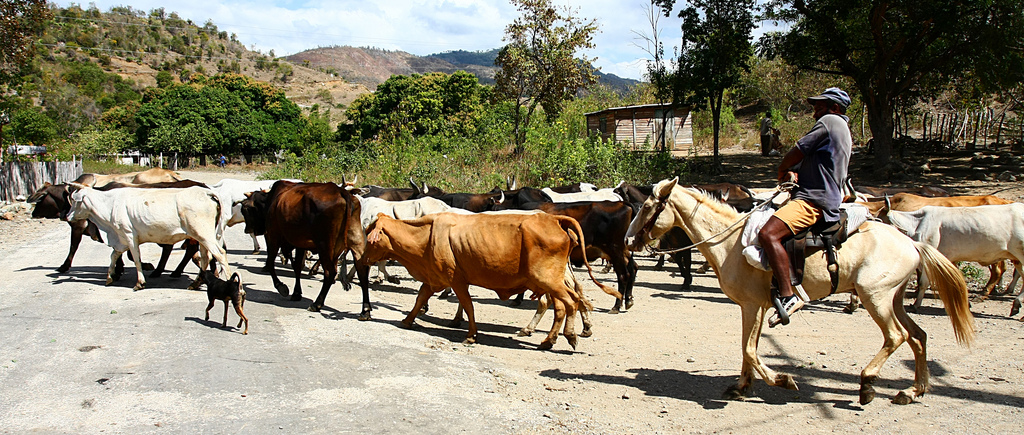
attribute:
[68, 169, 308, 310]
cow — white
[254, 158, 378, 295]
cow — dark, brown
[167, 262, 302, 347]
dog — brown, small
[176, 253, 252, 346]
dog — small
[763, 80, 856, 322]
man — blue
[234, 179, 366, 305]
cow — brown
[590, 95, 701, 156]
shack — wooden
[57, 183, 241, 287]
cow — white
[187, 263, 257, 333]
dog — small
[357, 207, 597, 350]
cow — tan, light brown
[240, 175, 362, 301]
cow — brown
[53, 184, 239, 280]
cow — white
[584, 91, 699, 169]
shed — wooden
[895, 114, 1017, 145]
fence — old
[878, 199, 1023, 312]
cow — white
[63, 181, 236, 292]
cow — white